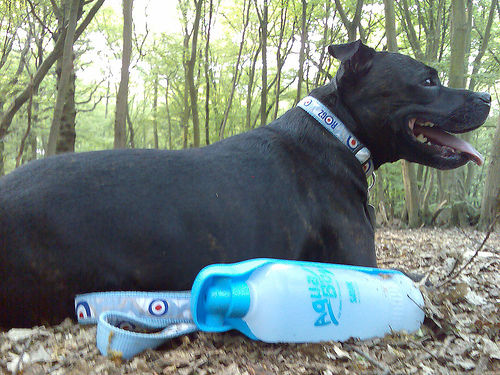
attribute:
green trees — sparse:
[141, 24, 245, 107]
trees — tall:
[7, 4, 271, 141]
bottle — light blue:
[181, 243, 461, 357]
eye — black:
[416, 74, 437, 88]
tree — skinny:
[116, 0, 130, 149]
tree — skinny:
[49, 2, 84, 154]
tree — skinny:
[186, 7, 205, 147]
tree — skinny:
[260, 2, 270, 124]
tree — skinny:
[294, 0, 309, 105]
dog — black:
[136, 42, 499, 233]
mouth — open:
[398, 104, 498, 179]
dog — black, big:
[6, 37, 493, 332]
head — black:
[324, 27, 479, 167]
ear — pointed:
[327, 38, 377, 78]